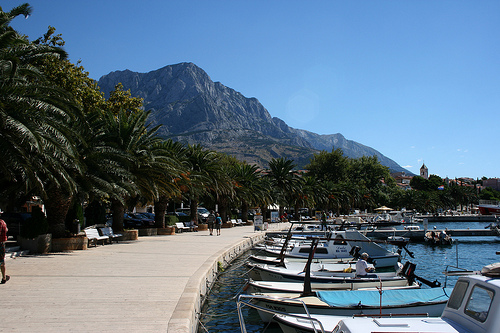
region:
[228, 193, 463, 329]
A row of boats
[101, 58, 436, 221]
A mountain is in the background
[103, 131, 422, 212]
Trees are in the background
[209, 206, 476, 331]
Boats are in water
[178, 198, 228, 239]
People are in the background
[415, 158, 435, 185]
Building is in the background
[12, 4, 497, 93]
Sky is clear in this image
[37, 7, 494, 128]
The sky is bright blue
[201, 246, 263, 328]
Boats are held by rope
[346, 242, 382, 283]
Person is sitting on the boat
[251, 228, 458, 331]
line of boats tied to wall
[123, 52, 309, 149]
rocky mountain in background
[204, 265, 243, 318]
ropes on docked boats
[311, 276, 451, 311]
blue cover on top of boat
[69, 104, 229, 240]
palm trees along sidewalk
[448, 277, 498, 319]
two front windows on boat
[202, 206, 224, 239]
couple strolling on sidewalk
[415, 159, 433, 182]
steeple of building in the distance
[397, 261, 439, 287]
motor on back of boat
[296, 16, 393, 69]
clear blue daytime sky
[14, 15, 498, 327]
beach with a lot of boats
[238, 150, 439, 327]
docked boats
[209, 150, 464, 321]
boardwalk with a lot of boats in the water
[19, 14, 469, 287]
blue water below a mountain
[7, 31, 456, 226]
palm trees in a row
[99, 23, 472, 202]
mountain in front of bright blue sky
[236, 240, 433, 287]
person sitting in a boat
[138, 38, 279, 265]
people walking on concrete in front of palm trees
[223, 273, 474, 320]
boat covered in a tarp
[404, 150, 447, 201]
tower in the distance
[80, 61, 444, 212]
a large mountain in the background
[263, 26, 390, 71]
a light blue sky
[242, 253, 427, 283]
a white boat in the water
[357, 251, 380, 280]
a man sitting in side of boat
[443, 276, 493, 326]
windows of white boat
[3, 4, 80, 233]
a small palm tree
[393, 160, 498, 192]
buildings in the background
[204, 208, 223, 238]
two people walking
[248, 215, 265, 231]
a white sign on walk way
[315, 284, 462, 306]
a blue tarp on boat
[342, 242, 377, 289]
man in white on a boat